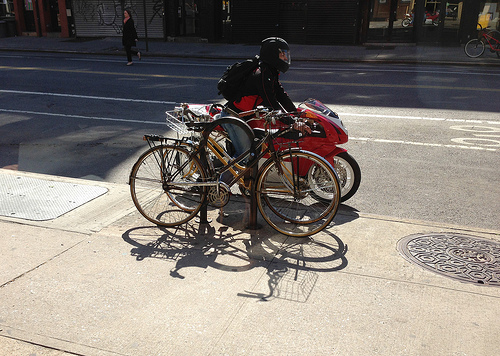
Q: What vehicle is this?
A: Bike.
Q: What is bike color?
A: Red.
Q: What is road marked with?
A: White line.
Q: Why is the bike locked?
A: To prevent theft.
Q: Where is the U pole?
A: On the sidewalk.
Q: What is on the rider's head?
A: A helmet.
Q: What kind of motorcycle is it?
A: A superbike.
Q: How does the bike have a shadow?
A: The sun shines on it.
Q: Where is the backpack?
A: On the rider's back.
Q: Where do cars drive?
A: Between the lines.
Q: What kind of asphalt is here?
A: The asphalt is black.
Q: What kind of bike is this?
A: This is a yellow bike.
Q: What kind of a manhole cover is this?
A: This is a metal manhole cover.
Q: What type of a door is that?
A: That is a mirrored door.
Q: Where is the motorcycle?
A: On the street.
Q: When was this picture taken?
A: During the day.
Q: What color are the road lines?
A: White.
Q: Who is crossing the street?
A: A woman.